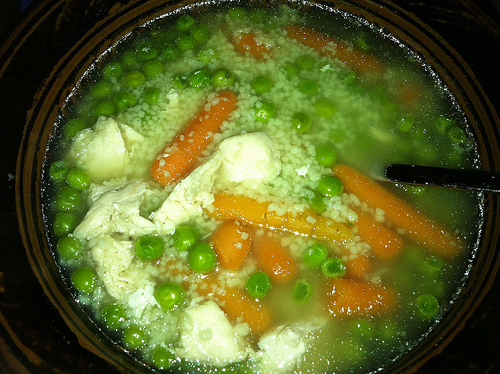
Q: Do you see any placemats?
A: No, there are no placemats.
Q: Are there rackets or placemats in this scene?
A: No, there are no placemats or rackets.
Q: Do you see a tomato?
A: No, there are no tomatoes.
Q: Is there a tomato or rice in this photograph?
A: No, there are no tomatoes or rice.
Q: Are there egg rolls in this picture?
A: No, there are no egg rolls.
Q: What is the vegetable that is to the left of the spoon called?
A: The vegetable is a pea.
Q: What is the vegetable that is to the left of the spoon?
A: The vegetable is a pea.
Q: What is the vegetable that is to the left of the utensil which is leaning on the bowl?
A: The vegetable is a pea.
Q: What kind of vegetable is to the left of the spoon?
A: The vegetable is a pea.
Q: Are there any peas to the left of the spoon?
A: Yes, there is a pea to the left of the spoon.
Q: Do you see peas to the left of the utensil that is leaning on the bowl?
A: Yes, there is a pea to the left of the spoon.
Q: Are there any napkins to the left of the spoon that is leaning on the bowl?
A: No, there is a pea to the left of the spoon.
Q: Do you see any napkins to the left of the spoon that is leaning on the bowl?
A: No, there is a pea to the left of the spoon.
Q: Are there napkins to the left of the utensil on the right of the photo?
A: No, there is a pea to the left of the spoon.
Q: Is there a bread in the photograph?
A: No, there is no breads.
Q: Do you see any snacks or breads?
A: No, there are no breads or snacks.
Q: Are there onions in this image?
A: No, there are no onions.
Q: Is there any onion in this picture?
A: No, there are no onions.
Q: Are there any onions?
A: No, there are no onions.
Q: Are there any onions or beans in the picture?
A: No, there are no onions or beans.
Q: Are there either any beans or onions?
A: No, there are no onions or beans.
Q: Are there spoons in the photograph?
A: Yes, there is a spoon.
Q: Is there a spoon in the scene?
A: Yes, there is a spoon.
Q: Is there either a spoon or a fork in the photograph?
A: Yes, there is a spoon.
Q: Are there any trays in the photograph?
A: No, there are no trays.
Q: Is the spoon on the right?
A: Yes, the spoon is on the right of the image.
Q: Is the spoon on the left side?
A: No, the spoon is on the right of the image.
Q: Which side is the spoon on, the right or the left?
A: The spoon is on the right of the image.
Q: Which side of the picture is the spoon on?
A: The spoon is on the right of the image.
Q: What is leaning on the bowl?
A: The spoon is leaning on the bowl.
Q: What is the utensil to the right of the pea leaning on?
A: The spoon is leaning on the bowl.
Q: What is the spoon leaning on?
A: The spoon is leaning on the bowl.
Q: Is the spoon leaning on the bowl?
A: Yes, the spoon is leaning on the bowl.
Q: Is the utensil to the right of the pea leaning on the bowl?
A: Yes, the spoon is leaning on the bowl.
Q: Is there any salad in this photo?
A: No, there is no salad.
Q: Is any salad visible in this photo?
A: No, there is no salad.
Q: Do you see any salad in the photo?
A: No, there is no salad.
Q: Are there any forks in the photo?
A: No, there are no forks.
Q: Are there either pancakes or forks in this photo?
A: No, there are no forks or pancakes.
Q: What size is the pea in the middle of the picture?
A: The pea is large.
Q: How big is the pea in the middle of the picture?
A: The pea is large.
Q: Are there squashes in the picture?
A: No, there are no squashes.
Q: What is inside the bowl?
A: The peas are inside the bowl.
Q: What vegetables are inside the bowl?
A: The vegetables are peas.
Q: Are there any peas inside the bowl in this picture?
A: Yes, there are peas inside the bowl.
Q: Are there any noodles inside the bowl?
A: No, there are peas inside the bowl.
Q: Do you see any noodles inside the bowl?
A: No, there are peas inside the bowl.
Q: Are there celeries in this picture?
A: No, there are no celeries.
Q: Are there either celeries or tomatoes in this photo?
A: No, there are no celeries or tomatoes.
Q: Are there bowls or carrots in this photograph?
A: Yes, there is a carrot.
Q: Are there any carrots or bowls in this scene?
A: Yes, there is a carrot.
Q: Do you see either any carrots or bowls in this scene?
A: Yes, there is a carrot.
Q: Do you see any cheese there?
A: No, there is no cheese.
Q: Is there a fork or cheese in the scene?
A: No, there are no cheese or forks.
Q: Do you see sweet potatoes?
A: No, there are no sweet potatoes.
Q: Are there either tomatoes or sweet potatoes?
A: No, there are no sweet potatoes or tomatoes.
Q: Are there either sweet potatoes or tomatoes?
A: No, there are no sweet potatoes or tomatoes.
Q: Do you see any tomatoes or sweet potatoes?
A: No, there are no sweet potatoes or tomatoes.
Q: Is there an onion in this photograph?
A: No, there are no onions.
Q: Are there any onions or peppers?
A: No, there are no onions or peppers.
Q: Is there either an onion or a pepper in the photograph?
A: No, there are no onions or peppers.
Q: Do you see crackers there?
A: No, there are no crackers.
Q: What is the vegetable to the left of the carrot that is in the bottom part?
A: The vegetable is a pea.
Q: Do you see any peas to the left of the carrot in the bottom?
A: Yes, there is a pea to the left of the carrot.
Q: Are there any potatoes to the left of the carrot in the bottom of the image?
A: No, there is a pea to the left of the carrot.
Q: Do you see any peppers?
A: No, there are no peppers.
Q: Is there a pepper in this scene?
A: No, there are no peppers.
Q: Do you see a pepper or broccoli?
A: No, there are no peppers or broccoli.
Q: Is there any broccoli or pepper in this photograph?
A: No, there are no peppers or broccoli.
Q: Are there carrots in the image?
A: Yes, there is a carrot.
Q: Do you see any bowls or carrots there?
A: Yes, there is a carrot.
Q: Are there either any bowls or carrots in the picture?
A: Yes, there is a carrot.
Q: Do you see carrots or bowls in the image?
A: Yes, there is a carrot.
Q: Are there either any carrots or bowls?
A: Yes, there is a carrot.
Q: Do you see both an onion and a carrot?
A: No, there is a carrot but no onions.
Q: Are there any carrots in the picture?
A: Yes, there is a carrot.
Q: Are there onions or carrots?
A: Yes, there is a carrot.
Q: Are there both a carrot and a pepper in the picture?
A: No, there is a carrot but no peppers.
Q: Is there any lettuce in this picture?
A: No, there is no lettuce.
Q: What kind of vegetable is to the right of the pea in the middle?
A: The vegetable is a carrot.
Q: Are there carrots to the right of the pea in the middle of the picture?
A: Yes, there is a carrot to the right of the pea.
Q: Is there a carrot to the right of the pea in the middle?
A: Yes, there is a carrot to the right of the pea.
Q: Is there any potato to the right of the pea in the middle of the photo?
A: No, there is a carrot to the right of the pea.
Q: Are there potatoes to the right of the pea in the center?
A: No, there is a carrot to the right of the pea.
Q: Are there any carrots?
A: Yes, there is a carrot.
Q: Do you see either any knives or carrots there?
A: Yes, there is a carrot.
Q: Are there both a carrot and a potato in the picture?
A: No, there is a carrot but no potatoes.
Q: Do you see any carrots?
A: Yes, there is a carrot.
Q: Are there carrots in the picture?
A: Yes, there is a carrot.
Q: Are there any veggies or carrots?
A: Yes, there is a carrot.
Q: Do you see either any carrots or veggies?
A: Yes, there is a carrot.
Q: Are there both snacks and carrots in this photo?
A: No, there is a carrot but no snacks.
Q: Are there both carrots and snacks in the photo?
A: No, there is a carrot but no snacks.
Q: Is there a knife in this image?
A: No, there are no knives.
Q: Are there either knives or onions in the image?
A: No, there are no knives or onions.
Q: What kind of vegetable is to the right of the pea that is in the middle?
A: The vegetable is a carrot.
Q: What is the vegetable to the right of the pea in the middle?
A: The vegetable is a carrot.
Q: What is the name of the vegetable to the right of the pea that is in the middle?
A: The vegetable is a carrot.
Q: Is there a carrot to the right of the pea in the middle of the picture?
A: Yes, there is a carrot to the right of the pea.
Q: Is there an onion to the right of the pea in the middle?
A: No, there is a carrot to the right of the pea.